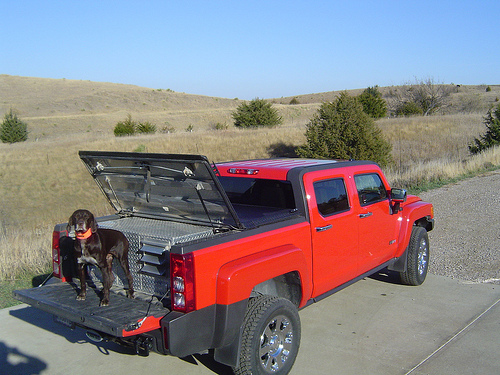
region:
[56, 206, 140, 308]
Dog standing on tailgate.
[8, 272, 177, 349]
The tailgate is open.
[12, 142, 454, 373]
Red truck is parked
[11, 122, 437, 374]
Truck sitting along the side of the road.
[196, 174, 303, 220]
Rear window of truck is tinted.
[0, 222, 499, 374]
Truck is sitting on concrete surface.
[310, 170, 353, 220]
Rear passenger window is tinted.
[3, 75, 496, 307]
Grass on hillside is brown.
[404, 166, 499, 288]
Road in front of truck is gravel.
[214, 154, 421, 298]
Truck has foour doors.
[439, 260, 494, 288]
small cracked line on the pavement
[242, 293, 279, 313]
grooves in black tire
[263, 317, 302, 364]
shiny silver rims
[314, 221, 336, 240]
silver door on red truck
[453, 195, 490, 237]
many gravel on the road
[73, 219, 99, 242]
red collar on the black dog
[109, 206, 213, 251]
silver top of tool box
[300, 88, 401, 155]
large green tree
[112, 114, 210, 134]
small cluster of small green trees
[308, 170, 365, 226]
black tint window in red truck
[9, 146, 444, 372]
A RED TRUCK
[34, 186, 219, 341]
A BLACK DOG ON THE BACK OF A TRUCK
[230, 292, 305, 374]
REAR TRUCK TIRE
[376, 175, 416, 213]
A SIDE VIEW MIRROR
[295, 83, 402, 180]
A GREEN BUSH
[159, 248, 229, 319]
A REAR RED BRAKE LIGHT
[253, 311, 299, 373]
A METAL HUB CAP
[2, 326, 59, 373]
A SHADOW ON THE GROUND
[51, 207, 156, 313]
A BLACK DOG LOOKING STRAIGHT AHEAD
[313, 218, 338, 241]
A METAL TRUCK DOOR HANDLE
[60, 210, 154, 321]
dog in a truck bed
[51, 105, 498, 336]
red truck with a dog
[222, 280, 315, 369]
big tires on a truck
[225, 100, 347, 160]
a bush in the background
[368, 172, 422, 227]
side view truck mirror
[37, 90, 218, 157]
grassy field with bushes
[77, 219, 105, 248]
dog wearing a red collar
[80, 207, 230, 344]
tool boxes in red truck bed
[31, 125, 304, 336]
canopy top is lifted in the back of the truck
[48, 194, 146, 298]
the dog has floppy ears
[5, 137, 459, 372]
A jeep is parked on the road.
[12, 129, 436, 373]
The jeep is red.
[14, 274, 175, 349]
The jeep's rear door is folded down.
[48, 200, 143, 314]
A dog stands on the back ramp.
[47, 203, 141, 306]
The dog is brown.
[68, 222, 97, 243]
The dog wears an orange collar.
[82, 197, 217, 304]
The jeep is carrying a metal box.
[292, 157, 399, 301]
The jeep's side has two doors.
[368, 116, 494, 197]
Grass grows along the road.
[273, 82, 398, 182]
Trees grow along the road.